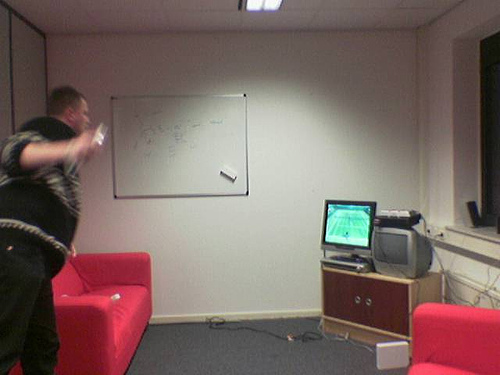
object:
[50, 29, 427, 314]
wall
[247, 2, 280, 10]
light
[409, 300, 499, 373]
chair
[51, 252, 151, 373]
chair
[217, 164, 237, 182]
eraser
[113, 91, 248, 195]
board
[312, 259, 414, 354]
cabinet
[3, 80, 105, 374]
man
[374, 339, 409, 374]
wii